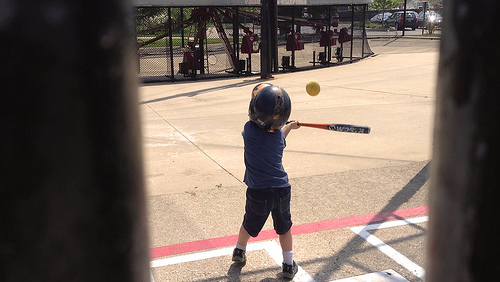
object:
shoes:
[233, 247, 299, 279]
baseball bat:
[285, 120, 370, 134]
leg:
[269, 185, 299, 279]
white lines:
[330, 268, 407, 282]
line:
[148, 202, 429, 267]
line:
[347, 225, 428, 280]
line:
[261, 237, 312, 282]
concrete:
[136, 37, 441, 278]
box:
[149, 203, 428, 282]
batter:
[232, 82, 300, 281]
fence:
[136, 2, 371, 81]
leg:
[232, 187, 269, 262]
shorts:
[241, 176, 292, 238]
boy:
[232, 83, 300, 278]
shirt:
[242, 118, 292, 188]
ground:
[137, 21, 443, 280]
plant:
[185, 185, 199, 196]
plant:
[215, 182, 222, 187]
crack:
[146, 182, 244, 197]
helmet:
[248, 82, 292, 131]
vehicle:
[383, 11, 418, 31]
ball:
[305, 81, 320, 97]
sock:
[283, 250, 295, 266]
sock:
[236, 242, 246, 251]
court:
[139, 45, 431, 281]